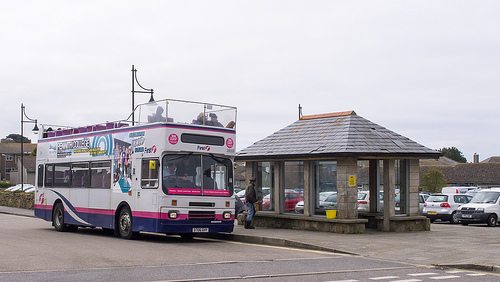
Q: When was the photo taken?
A: Day time.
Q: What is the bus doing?
A: Parked.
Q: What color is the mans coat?
A: Black.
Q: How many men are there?
A: One.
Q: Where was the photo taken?
A: At a toll booth.